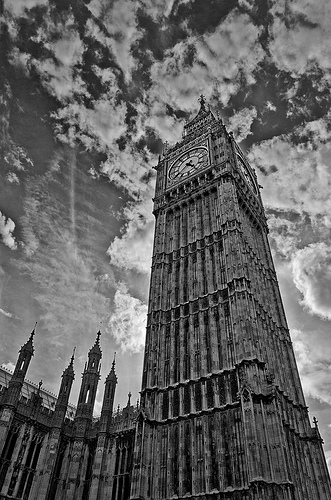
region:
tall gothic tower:
[129, 95, 329, 498]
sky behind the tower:
[0, 0, 330, 471]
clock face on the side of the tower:
[167, 147, 210, 180]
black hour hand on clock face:
[184, 161, 198, 170]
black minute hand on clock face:
[171, 160, 193, 178]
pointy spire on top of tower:
[184, 93, 210, 126]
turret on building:
[2, 320, 41, 404]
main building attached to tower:
[1, 364, 138, 498]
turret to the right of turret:
[49, 345, 77, 424]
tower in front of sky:
[129, 92, 329, 499]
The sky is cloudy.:
[4, 2, 325, 319]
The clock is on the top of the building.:
[163, 148, 209, 181]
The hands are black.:
[165, 150, 210, 180]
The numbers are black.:
[162, 146, 217, 178]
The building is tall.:
[154, 91, 293, 429]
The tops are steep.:
[12, 316, 130, 383]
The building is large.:
[11, 370, 298, 499]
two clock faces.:
[158, 126, 269, 195]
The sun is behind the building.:
[23, 23, 325, 400]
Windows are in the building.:
[9, 329, 134, 423]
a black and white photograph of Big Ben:
[7, 7, 316, 493]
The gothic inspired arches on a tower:
[129, 195, 290, 492]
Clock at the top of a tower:
[135, 88, 270, 203]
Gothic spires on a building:
[0, 309, 145, 427]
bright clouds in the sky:
[79, 0, 329, 347]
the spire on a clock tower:
[186, 92, 219, 115]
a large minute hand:
[167, 165, 190, 178]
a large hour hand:
[187, 161, 198, 170]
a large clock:
[158, 138, 221, 185]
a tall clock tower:
[137, 92, 320, 498]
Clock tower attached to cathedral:
[128, 93, 329, 498]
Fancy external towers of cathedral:
[1, 320, 120, 498]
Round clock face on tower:
[167, 144, 210, 182]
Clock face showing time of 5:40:
[166, 145, 210, 183]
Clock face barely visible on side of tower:
[233, 151, 258, 198]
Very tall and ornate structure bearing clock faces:
[127, 93, 326, 497]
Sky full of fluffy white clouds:
[0, 0, 329, 476]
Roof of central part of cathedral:
[1, 365, 77, 419]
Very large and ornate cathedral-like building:
[0, 93, 329, 498]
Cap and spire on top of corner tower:
[87, 329, 102, 358]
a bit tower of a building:
[19, 91, 326, 498]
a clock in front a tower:
[159, 142, 213, 190]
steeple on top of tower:
[167, 86, 232, 142]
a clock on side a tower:
[221, 140, 266, 199]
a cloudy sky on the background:
[27, 39, 323, 299]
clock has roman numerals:
[167, 141, 212, 184]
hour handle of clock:
[186, 155, 202, 172]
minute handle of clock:
[173, 158, 189, 179]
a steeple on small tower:
[13, 317, 46, 358]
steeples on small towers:
[56, 324, 125, 395]